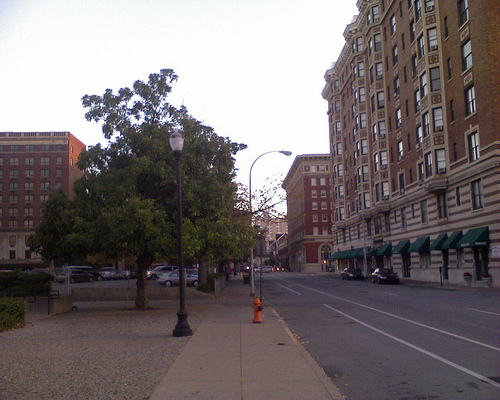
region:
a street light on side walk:
[242, 135, 302, 285]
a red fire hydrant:
[247, 289, 267, 327]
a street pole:
[160, 117, 202, 346]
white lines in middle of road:
[279, 270, 486, 393]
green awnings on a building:
[311, 225, 498, 293]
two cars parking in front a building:
[331, 260, 408, 290]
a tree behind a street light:
[24, 66, 268, 328]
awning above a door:
[456, 223, 496, 286]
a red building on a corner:
[274, 146, 337, 285]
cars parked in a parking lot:
[61, 253, 216, 300]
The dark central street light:
[165, 126, 192, 336]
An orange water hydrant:
[251, 297, 265, 324]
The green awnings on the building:
[331, 229, 493, 261]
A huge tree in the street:
[27, 69, 287, 321]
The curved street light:
[247, 145, 294, 299]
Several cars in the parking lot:
[4, 262, 209, 291]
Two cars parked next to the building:
[339, 264, 399, 285]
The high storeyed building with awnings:
[322, 0, 497, 285]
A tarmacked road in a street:
[250, 260, 497, 397]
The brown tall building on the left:
[0, 132, 87, 272]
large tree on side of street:
[18, 58, 268, 331]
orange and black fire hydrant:
[238, 285, 310, 369]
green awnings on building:
[319, 225, 494, 297]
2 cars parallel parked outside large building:
[321, 247, 405, 290]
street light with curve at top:
[235, 144, 303, 299]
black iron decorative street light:
[153, 115, 215, 342]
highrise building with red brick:
[2, 110, 103, 281]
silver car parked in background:
[160, 263, 207, 289]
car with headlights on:
[268, 253, 291, 281]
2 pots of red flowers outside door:
[460, 261, 497, 293]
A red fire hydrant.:
[250, 297, 265, 324]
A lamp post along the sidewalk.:
[166, 128, 193, 336]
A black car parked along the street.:
[369, 268, 398, 281]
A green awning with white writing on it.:
[456, 227, 490, 249]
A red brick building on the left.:
[1, 130, 87, 271]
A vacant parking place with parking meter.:
[438, 265, 443, 290]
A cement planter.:
[463, 271, 473, 286]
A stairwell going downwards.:
[23, 290, 57, 319]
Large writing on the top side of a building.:
[1, 130, 67, 137]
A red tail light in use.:
[270, 265, 274, 272]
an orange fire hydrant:
[250, 296, 265, 323]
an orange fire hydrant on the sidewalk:
[250, 297, 266, 324]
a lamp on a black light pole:
[167, 128, 193, 337]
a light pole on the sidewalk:
[167, 125, 192, 336]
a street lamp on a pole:
[247, 149, 292, 293]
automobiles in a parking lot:
[52, 263, 202, 288]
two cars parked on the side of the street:
[336, 264, 497, 399]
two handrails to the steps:
[12, 287, 59, 316]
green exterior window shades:
[327, 225, 497, 264]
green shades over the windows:
[327, 225, 489, 260]